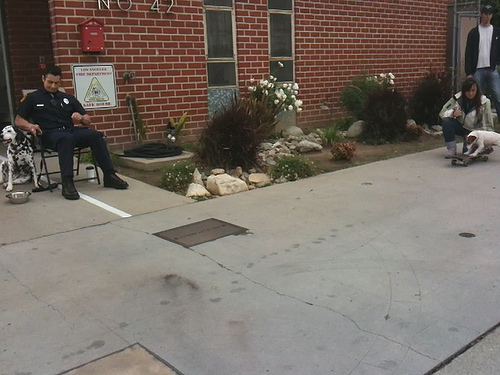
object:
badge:
[63, 98, 70, 105]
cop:
[12, 65, 128, 201]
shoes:
[61, 178, 79, 200]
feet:
[58, 135, 79, 199]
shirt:
[18, 86, 88, 128]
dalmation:
[16, 151, 26, 163]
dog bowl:
[6, 191, 30, 204]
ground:
[0, 183, 499, 372]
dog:
[0, 124, 40, 192]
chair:
[23, 87, 102, 193]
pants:
[41, 125, 114, 175]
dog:
[462, 129, 500, 157]